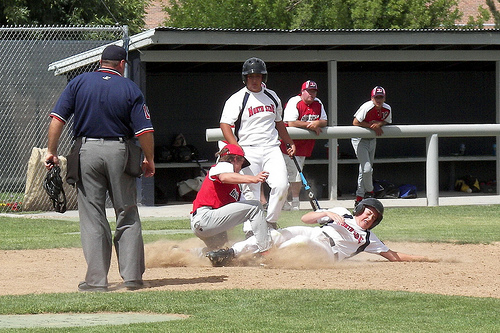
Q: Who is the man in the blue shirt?
A: The umpire.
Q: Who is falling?
A: Baseball player.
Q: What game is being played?
A: Baseball.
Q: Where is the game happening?
A: Baseball field.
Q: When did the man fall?
A: Just now.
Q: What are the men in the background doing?
A: Leaning over.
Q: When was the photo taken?
A: During the daytime.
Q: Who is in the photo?
A: Some people.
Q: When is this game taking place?
A: During the day.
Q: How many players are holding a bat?
A: One.